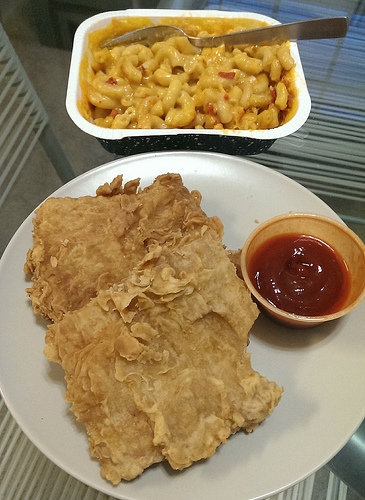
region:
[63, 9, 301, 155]
bowl of mac and cheese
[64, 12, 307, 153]
paper bowl with mac and cheese in it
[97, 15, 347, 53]
metal fork in the mac and cheese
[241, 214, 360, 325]
small plastic cup full of ketchup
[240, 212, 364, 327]
ketchup in a plastic cup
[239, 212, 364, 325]
cup of ketchup on the plate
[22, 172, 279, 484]
fried food on the plate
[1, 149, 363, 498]
white plate with food on it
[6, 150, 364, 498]
white plate on the table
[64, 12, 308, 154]
mac and cheese next to the plate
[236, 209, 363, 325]
A plastic container of ketchup.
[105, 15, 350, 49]
A fork in macaroni.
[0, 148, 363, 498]
A round white plate.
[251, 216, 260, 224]
A crumb on a plate.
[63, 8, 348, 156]
A container of food.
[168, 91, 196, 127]
A cheesy macaroni noodle.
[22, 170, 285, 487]
A crispy piece of meat.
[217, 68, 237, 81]
A red flake in mac and cheese.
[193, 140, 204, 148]
A spot on container.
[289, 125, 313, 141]
A reflection of a fork on a table.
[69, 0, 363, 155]
cheesy macaroni and cheese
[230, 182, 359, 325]
ketchup on plastic cup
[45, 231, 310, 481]
piece of fried chicken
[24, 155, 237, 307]
piece of fried chicken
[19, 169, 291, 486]
two pieces of fried chicken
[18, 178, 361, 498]
fried chicken and ketchup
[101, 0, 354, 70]
metal fork in macaroni and cheese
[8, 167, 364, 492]
fried chicken on plate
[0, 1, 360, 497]
food plates on glass table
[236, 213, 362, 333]
ketchup cup on plate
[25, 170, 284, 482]
A large chicken breast laying on a plate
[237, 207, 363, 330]
A container holding dipping sauce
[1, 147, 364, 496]
A white plate containing food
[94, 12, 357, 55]
A silver fork in macaroni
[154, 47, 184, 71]
A chessy macaroni noodle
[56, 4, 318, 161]
A container full of macaroni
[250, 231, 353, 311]
A red dipping sauce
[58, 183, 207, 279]
Brown chicken skin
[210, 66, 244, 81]
A bacon bit in macaroni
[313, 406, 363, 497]
A grey bar holding the table up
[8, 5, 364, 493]
a table with plates of food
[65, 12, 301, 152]
a bowl with macaroni and cheese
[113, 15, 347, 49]
fork stuck in the macaroni and cheese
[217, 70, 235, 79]
little bacon on the Mac and cheese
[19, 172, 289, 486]
crispy breaded boneless chicken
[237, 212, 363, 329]
dipping sauce for chicken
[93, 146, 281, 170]
tip of the plate the chicken is in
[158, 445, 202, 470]
tip of the breaded boneless chicken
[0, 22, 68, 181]
chair on the side of the table where chicken is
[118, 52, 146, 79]
peice of macoroni in the bowl